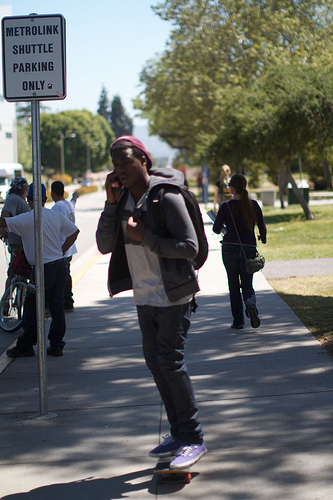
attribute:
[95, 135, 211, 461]
man — young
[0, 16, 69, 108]
sign — white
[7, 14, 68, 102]
border — black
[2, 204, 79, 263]
t-shirt — white